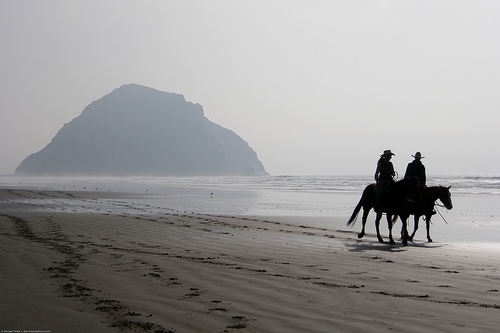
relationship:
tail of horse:
[340, 198, 365, 232] [346, 179, 424, 246]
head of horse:
[399, 175, 425, 198] [346, 179, 424, 246]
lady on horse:
[374, 149, 397, 185] [346, 179, 424, 246]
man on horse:
[407, 153, 429, 183] [405, 184, 454, 240]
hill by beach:
[15, 77, 271, 185] [2, 208, 496, 332]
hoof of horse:
[357, 232, 365, 240] [346, 179, 424, 246]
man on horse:
[407, 153, 429, 183] [346, 179, 424, 246]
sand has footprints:
[2, 186, 162, 220] [124, 201, 154, 212]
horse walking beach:
[346, 179, 424, 246] [2, 208, 496, 332]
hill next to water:
[15, 77, 271, 185] [144, 165, 494, 190]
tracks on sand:
[11, 208, 41, 238] [2, 186, 162, 220]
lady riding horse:
[374, 149, 397, 185] [346, 179, 424, 246]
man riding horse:
[407, 153, 429, 183] [346, 179, 424, 246]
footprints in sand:
[124, 201, 154, 212] [2, 186, 162, 220]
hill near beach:
[15, 77, 271, 185] [2, 208, 496, 332]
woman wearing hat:
[374, 149, 397, 185] [382, 148, 395, 157]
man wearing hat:
[407, 153, 429, 183] [382, 148, 395, 157]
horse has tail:
[346, 179, 424, 246] [340, 198, 365, 232]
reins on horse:
[435, 200, 443, 213] [405, 184, 454, 240]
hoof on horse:
[357, 232, 365, 240] [346, 179, 424, 246]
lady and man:
[374, 149, 397, 185] [407, 153, 429, 183]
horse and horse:
[346, 179, 424, 246] [405, 184, 454, 240]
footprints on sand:
[124, 201, 154, 212] [2, 186, 162, 220]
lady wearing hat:
[374, 149, 397, 185] [382, 148, 395, 157]